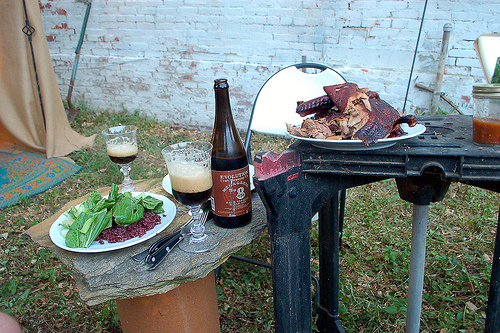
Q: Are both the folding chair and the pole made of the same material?
A: Yes, both the folding chair and the pole are made of metal.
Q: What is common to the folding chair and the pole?
A: The material, both the folding chair and the pole are metallic.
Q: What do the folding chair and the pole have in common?
A: The material, both the folding chair and the pole are metallic.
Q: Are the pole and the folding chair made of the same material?
A: Yes, both the pole and the folding chair are made of metal.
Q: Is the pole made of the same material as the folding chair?
A: Yes, both the pole and the folding chair are made of metal.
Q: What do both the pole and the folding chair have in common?
A: The material, both the pole and the folding chair are metallic.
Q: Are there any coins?
A: No, there are no coins.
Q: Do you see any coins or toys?
A: No, there are no coins or toys.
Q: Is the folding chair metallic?
A: Yes, the folding chair is metallic.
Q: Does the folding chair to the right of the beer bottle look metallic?
A: Yes, the folding chair is metallic.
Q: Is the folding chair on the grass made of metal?
A: Yes, the folding chair is made of metal.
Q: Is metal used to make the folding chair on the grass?
A: Yes, the folding chair is made of metal.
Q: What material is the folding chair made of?
A: The folding chair is made of metal.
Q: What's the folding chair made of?
A: The folding chair is made of metal.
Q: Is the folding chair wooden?
A: No, the folding chair is metallic.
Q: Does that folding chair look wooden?
A: No, the folding chair is metallic.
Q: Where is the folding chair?
A: The folding chair is on the grass.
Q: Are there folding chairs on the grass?
A: Yes, there is a folding chair on the grass.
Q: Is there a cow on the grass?
A: No, there is a folding chair on the grass.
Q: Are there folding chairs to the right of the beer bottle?
A: Yes, there is a folding chair to the right of the beer bottle.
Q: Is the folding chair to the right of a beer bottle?
A: Yes, the folding chair is to the right of a beer bottle.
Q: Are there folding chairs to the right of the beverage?
A: Yes, there is a folding chair to the right of the beverage.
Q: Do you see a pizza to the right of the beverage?
A: No, there is a folding chair to the right of the beverage.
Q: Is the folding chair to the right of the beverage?
A: Yes, the folding chair is to the right of the beverage.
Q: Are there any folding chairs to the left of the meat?
A: Yes, there is a folding chair to the left of the meat.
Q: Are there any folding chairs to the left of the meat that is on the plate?
A: Yes, there is a folding chair to the left of the meat.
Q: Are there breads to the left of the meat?
A: No, there is a folding chair to the left of the meat.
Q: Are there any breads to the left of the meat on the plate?
A: No, there is a folding chair to the left of the meat.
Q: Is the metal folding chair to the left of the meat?
A: Yes, the folding chair is to the left of the meat.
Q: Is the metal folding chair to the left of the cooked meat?
A: Yes, the folding chair is to the left of the meat.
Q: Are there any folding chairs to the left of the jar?
A: Yes, there is a folding chair to the left of the jar.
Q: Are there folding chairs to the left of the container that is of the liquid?
A: Yes, there is a folding chair to the left of the jar.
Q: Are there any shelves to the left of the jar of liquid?
A: No, there is a folding chair to the left of the jar.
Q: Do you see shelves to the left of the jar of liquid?
A: No, there is a folding chair to the left of the jar.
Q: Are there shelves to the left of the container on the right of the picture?
A: No, there is a folding chair to the left of the jar.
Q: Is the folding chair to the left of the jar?
A: Yes, the folding chair is to the left of the jar.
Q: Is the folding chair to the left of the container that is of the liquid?
A: Yes, the folding chair is to the left of the jar.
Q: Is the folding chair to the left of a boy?
A: No, the folding chair is to the left of the jar.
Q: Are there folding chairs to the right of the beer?
A: Yes, there is a folding chair to the right of the beer.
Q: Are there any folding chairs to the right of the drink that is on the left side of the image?
A: Yes, there is a folding chair to the right of the beer.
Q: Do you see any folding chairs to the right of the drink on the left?
A: Yes, there is a folding chair to the right of the beer.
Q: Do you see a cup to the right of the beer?
A: No, there is a folding chair to the right of the beer.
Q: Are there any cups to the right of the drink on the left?
A: No, there is a folding chair to the right of the beer.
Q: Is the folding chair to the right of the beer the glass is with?
A: Yes, the folding chair is to the right of the beer.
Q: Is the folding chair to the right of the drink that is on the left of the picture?
A: Yes, the folding chair is to the right of the beer.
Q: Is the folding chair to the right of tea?
A: No, the folding chair is to the right of the beer.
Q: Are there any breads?
A: No, there are no breads.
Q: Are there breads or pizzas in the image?
A: No, there are no breads or pizzas.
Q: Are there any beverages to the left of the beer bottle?
A: Yes, there is a beverage to the left of the beer bottle.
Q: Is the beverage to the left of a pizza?
A: No, the beverage is to the left of the beer bottle.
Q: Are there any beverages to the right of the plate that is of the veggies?
A: Yes, there is a beverage to the right of the plate.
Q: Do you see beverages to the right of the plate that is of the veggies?
A: Yes, there is a beverage to the right of the plate.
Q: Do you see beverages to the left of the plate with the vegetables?
A: No, the beverage is to the right of the plate.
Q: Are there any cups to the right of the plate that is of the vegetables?
A: No, there is a beverage to the right of the plate.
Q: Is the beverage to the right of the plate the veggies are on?
A: Yes, the beverage is to the right of the plate.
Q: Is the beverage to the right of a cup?
A: No, the beverage is to the right of the plate.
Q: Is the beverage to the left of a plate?
A: No, the beverage is to the right of a plate.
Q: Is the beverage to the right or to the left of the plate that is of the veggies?
A: The beverage is to the right of the plate.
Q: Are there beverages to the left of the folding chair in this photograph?
A: Yes, there is a beverage to the left of the folding chair.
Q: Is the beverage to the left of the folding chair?
A: Yes, the beverage is to the left of the folding chair.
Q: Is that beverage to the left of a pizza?
A: No, the beverage is to the left of the folding chair.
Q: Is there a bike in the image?
A: No, there are no bikes.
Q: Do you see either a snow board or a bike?
A: No, there are no bikes or snowboards.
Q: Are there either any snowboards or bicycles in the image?
A: No, there are no bicycles or snowboards.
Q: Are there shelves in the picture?
A: No, there are no shelves.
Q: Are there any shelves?
A: No, there are no shelves.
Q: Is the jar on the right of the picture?
A: Yes, the jar is on the right of the image.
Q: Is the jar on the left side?
A: No, the jar is on the right of the image.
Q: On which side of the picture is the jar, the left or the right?
A: The jar is on the right of the image.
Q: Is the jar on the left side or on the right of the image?
A: The jar is on the right of the image.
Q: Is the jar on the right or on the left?
A: The jar is on the right of the image.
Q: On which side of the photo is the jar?
A: The jar is on the right of the image.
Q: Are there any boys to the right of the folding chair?
A: No, there is a jar to the right of the folding chair.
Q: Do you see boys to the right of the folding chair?
A: No, there is a jar to the right of the folding chair.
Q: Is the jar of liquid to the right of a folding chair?
A: Yes, the jar is to the right of a folding chair.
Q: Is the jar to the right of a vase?
A: No, the jar is to the right of a folding chair.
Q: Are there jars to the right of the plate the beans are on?
A: Yes, there is a jar to the right of the plate.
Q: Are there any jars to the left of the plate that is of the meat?
A: No, the jar is to the right of the plate.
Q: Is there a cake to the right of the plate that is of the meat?
A: No, there is a jar to the right of the plate.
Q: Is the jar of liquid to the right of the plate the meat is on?
A: Yes, the jar is to the right of the plate.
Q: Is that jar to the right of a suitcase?
A: No, the jar is to the right of the plate.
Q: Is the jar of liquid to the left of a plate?
A: No, the jar is to the right of a plate.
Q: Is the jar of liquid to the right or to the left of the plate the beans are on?
A: The jar is to the right of the plate.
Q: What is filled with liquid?
A: The jar is filled with liquid.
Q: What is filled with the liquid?
A: The jar is filled with liquid.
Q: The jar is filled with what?
A: The jar is filled with liquid.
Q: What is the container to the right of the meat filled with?
A: The jar is filled with liquid.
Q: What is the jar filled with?
A: The jar is filled with liquid.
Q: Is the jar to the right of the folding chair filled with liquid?
A: Yes, the jar is filled with liquid.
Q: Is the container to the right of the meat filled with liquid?
A: Yes, the jar is filled with liquid.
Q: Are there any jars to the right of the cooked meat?
A: Yes, there is a jar to the right of the meat.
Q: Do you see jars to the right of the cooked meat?
A: Yes, there is a jar to the right of the meat.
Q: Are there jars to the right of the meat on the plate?
A: Yes, there is a jar to the right of the meat.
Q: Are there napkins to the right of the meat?
A: No, there is a jar to the right of the meat.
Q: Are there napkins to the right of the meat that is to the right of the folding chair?
A: No, there is a jar to the right of the meat.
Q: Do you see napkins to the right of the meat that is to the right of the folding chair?
A: No, there is a jar to the right of the meat.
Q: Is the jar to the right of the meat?
A: Yes, the jar is to the right of the meat.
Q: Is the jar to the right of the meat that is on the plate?
A: Yes, the jar is to the right of the meat.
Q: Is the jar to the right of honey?
A: No, the jar is to the right of the meat.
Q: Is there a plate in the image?
A: Yes, there is a plate.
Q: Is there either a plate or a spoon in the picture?
A: Yes, there is a plate.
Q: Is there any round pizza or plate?
A: Yes, there is a round plate.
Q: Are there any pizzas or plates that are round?
A: Yes, the plate is round.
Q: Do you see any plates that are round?
A: Yes, there is a round plate.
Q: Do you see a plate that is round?
A: Yes, there is a plate that is round.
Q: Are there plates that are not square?
A: Yes, there is a round plate.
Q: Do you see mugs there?
A: No, there are no mugs.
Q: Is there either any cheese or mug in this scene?
A: No, there are no mugs or cheese.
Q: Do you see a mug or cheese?
A: No, there are no mugs or cheese.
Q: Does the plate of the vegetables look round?
A: Yes, the plate is round.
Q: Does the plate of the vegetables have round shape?
A: Yes, the plate is round.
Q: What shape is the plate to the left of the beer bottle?
A: The plate is round.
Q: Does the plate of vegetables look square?
A: No, the plate is round.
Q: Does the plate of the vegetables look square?
A: No, the plate is round.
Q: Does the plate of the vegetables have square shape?
A: No, the plate is round.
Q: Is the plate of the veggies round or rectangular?
A: The plate is round.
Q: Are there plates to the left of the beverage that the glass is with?
A: Yes, there is a plate to the left of the beverage.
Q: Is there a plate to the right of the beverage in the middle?
A: No, the plate is to the left of the beverage.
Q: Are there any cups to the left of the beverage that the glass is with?
A: No, there is a plate to the left of the beverage.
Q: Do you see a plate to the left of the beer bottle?
A: Yes, there is a plate to the left of the beer bottle.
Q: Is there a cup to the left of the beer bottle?
A: No, there is a plate to the left of the beer bottle.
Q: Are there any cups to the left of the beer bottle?
A: No, there is a plate to the left of the beer bottle.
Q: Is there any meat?
A: Yes, there is meat.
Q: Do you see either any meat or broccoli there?
A: Yes, there is meat.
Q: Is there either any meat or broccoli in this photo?
A: Yes, there is meat.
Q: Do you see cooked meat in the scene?
A: Yes, there is cooked meat.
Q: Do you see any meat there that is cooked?
A: Yes, there is meat that is cooked.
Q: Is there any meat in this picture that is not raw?
A: Yes, there is cooked meat.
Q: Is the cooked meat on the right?
A: Yes, the meat is on the right of the image.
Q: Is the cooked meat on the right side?
A: Yes, the meat is on the right of the image.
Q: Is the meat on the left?
A: No, the meat is on the right of the image.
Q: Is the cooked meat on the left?
A: No, the meat is on the right of the image.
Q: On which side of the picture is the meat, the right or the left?
A: The meat is on the right of the image.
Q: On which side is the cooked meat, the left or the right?
A: The meat is on the right of the image.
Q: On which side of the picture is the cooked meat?
A: The meat is on the right of the image.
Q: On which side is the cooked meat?
A: The meat is on the right of the image.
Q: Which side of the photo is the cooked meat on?
A: The meat is on the right of the image.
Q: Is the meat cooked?
A: Yes, the meat is cooked.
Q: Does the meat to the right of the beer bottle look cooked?
A: Yes, the meat is cooked.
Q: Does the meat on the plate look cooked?
A: Yes, the meat is cooked.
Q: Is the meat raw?
A: No, the meat is cooked.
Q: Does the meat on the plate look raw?
A: No, the meat is cooked.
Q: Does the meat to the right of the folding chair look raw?
A: No, the meat is cooked.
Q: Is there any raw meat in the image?
A: No, there is meat but it is cooked.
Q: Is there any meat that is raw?
A: No, there is meat but it is cooked.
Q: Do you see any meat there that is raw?
A: No, there is meat but it is cooked.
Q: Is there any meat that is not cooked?
A: No, there is meat but it is cooked.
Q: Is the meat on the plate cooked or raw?
A: The meat is cooked.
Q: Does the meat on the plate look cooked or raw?
A: The meat is cooked.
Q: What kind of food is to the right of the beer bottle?
A: The food is meat.